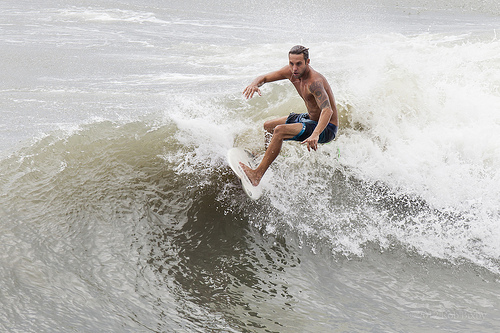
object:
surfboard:
[216, 128, 260, 195]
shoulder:
[307, 77, 325, 95]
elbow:
[320, 103, 334, 121]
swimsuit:
[284, 112, 335, 149]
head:
[287, 47, 308, 77]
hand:
[301, 134, 319, 151]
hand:
[244, 87, 265, 100]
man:
[238, 45, 343, 185]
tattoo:
[306, 78, 330, 110]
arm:
[299, 79, 332, 151]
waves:
[322, 23, 499, 262]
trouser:
[290, 118, 335, 142]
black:
[303, 121, 335, 144]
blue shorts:
[282, 102, 337, 149]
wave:
[157, 25, 496, 270]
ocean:
[2, 0, 499, 327]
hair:
[290, 45, 308, 62]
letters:
[235, 165, 253, 183]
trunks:
[282, 107, 337, 144]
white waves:
[318, 29, 499, 216]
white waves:
[166, 44, 264, 153]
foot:
[231, 153, 269, 193]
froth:
[332, 20, 499, 224]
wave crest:
[174, 31, 499, 265]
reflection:
[155, 152, 300, 331]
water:
[7, 3, 495, 332]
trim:
[294, 114, 304, 138]